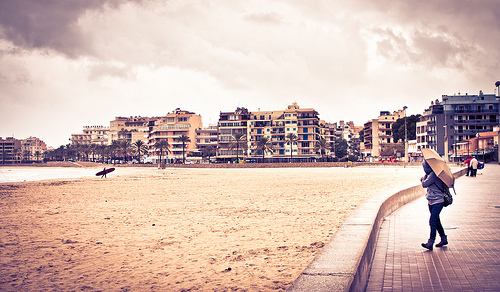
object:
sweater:
[421, 172, 451, 205]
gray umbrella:
[422, 148, 457, 195]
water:
[0, 168, 91, 179]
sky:
[1, 2, 498, 154]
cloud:
[1, 0, 121, 60]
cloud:
[371, 27, 423, 67]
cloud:
[358, 0, 499, 85]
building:
[417, 92, 498, 164]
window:
[251, 122, 254, 125]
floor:
[168, 182, 288, 282]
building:
[1, 135, 46, 167]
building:
[45, 122, 105, 161]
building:
[105, 108, 201, 161]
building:
[193, 103, 335, 165]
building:
[341, 105, 409, 164]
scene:
[0, 0, 497, 289]